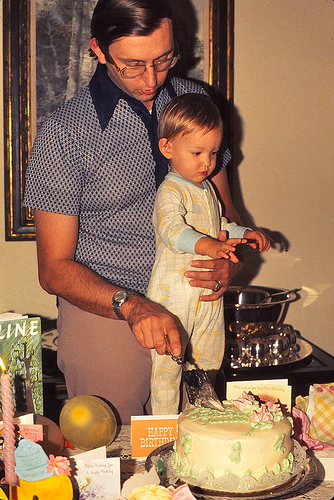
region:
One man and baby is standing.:
[49, 25, 236, 228]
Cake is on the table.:
[177, 394, 313, 486]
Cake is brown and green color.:
[178, 398, 284, 476]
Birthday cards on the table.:
[21, 393, 328, 495]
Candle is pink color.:
[1, 362, 27, 487]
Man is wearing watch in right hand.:
[105, 287, 151, 318]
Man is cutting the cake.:
[106, 120, 314, 478]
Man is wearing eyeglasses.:
[98, 46, 189, 87]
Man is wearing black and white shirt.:
[60, 126, 166, 205]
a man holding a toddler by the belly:
[69, 15, 229, 360]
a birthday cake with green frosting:
[178, 398, 296, 482]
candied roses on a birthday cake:
[236, 392, 283, 431]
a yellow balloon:
[65, 389, 119, 444]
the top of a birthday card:
[227, 377, 293, 393]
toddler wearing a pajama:
[156, 104, 233, 330]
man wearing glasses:
[107, 53, 182, 78]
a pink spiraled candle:
[0, 350, 23, 496]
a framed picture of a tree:
[1, 1, 88, 77]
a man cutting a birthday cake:
[78, 15, 218, 462]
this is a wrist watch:
[111, 291, 127, 307]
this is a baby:
[165, 96, 222, 278]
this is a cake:
[192, 409, 285, 478]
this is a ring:
[214, 282, 221, 290]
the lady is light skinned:
[42, 221, 71, 253]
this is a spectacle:
[117, 63, 177, 68]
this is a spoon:
[267, 287, 294, 294]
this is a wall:
[276, 160, 316, 225]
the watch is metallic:
[113, 303, 123, 320]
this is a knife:
[178, 357, 204, 392]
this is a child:
[147, 98, 236, 293]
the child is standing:
[147, 100, 230, 295]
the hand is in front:
[203, 228, 246, 260]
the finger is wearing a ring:
[210, 278, 223, 290]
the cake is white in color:
[182, 405, 293, 477]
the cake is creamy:
[173, 399, 293, 481]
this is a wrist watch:
[110, 287, 136, 314]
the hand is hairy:
[74, 281, 93, 299]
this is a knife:
[176, 363, 214, 403]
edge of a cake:
[200, 431, 233, 453]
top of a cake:
[247, 411, 266, 432]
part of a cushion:
[118, 357, 144, 384]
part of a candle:
[3, 403, 34, 433]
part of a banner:
[130, 412, 158, 437]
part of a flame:
[3, 365, 6, 368]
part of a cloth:
[301, 382, 328, 421]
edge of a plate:
[292, 470, 321, 486]